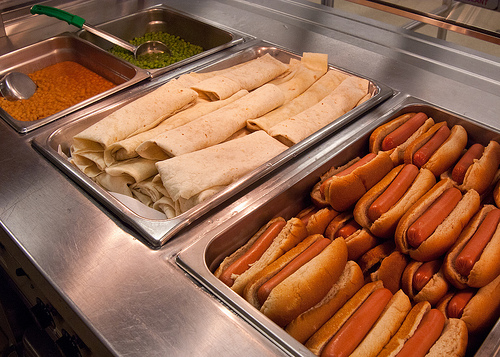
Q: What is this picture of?
A: A buffet.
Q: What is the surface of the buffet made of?
A: Metal.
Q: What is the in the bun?
A: A hot dog.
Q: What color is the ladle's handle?
A: Green.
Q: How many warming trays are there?
A: Four.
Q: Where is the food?
A: On the buffet.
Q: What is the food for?
A: Eating.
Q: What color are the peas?
A: Green.